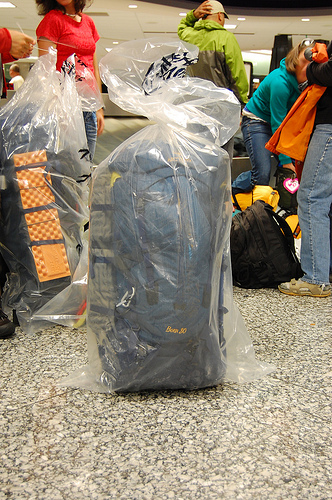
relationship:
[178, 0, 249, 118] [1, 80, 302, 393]
man with luggage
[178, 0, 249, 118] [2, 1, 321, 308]
man wait in line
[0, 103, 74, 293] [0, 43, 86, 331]
pack wrapped in plastic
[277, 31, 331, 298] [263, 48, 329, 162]
person clutches jacket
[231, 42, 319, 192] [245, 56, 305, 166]
traveler wearing hoodie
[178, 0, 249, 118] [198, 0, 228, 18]
man wearing cap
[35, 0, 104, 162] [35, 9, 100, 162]
woman wearing shirt and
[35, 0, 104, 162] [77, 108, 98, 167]
woman wearing blue jeans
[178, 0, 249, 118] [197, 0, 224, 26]
man rubbing head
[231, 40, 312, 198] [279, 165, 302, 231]
traveler picking up luggage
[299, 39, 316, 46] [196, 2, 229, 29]
sunglasses on head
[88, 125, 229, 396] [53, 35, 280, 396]
bag in plastic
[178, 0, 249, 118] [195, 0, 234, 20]
man wearing hat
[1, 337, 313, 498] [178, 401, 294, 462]
tiles on floor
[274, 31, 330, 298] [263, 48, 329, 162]
person holding jacket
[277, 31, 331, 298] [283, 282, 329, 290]
person wearing socks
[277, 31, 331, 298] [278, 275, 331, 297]
person wearing sandals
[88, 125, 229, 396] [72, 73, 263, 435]
bag inside bag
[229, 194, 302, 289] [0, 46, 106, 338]
backpack inside plastic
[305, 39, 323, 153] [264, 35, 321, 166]
arm holding jacket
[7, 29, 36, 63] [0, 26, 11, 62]
hands with sleeves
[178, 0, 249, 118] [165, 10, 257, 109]
man wearing jacket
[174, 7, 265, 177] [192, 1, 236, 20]
man wearing cap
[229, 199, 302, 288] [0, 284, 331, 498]
backpack on floor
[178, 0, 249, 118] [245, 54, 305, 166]
man wearing hoodie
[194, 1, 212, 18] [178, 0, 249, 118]
hand on man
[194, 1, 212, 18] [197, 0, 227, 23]
hand on head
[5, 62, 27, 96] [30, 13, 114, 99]
person wearing shirt